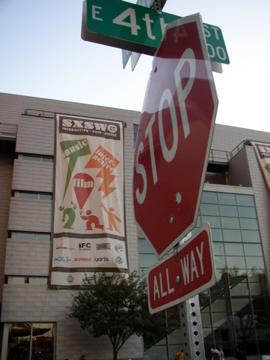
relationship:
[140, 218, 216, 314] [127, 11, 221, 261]
sign under sign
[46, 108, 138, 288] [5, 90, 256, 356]
ad on building